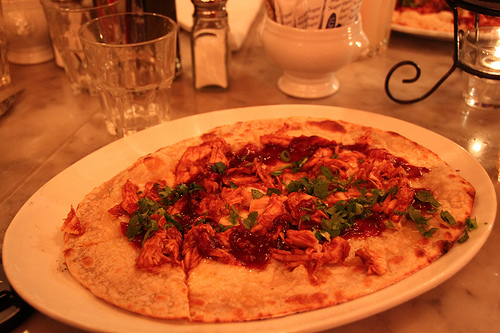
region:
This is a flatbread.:
[45, 75, 477, 328]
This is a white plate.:
[6, 79, 499, 329]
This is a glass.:
[79, 10, 183, 147]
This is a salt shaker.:
[183, 0, 245, 97]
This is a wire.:
[377, 42, 457, 103]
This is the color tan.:
[88, 245, 113, 270]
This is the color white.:
[37, 269, 74, 302]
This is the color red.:
[150, 238, 165, 251]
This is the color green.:
[330, 206, 348, 226]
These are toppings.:
[168, 141, 360, 250]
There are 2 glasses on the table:
[42, 5, 176, 128]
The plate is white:
[67, 126, 465, 292]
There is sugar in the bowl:
[243, 9, 382, 91]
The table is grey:
[367, 62, 489, 184]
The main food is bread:
[128, 138, 431, 299]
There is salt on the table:
[187, 5, 238, 92]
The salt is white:
[187, 10, 254, 110]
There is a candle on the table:
[426, 17, 498, 94]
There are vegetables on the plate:
[135, 162, 475, 239]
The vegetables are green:
[144, 166, 448, 286]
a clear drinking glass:
[78, 8, 177, 128]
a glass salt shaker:
[183, 0, 226, 90]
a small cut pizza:
[61, 130, 460, 327]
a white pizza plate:
[0, 96, 480, 322]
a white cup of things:
[259, 4, 381, 95]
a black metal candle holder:
[378, 0, 499, 107]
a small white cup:
[0, 0, 61, 67]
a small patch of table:
[14, 109, 64, 182]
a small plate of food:
[387, 5, 497, 34]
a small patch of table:
[455, 264, 494, 329]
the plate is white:
[83, 135, 498, 305]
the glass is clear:
[73, 39, 177, 115]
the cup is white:
[268, 37, 355, 84]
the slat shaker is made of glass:
[191, 23, 244, 88]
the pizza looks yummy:
[93, 110, 467, 308]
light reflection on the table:
[461, 115, 498, 150]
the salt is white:
[193, 35, 239, 85]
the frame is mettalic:
[391, 37, 475, 99]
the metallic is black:
[371, 47, 456, 104]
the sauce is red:
[216, 226, 300, 273]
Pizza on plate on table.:
[50, 108, 482, 331]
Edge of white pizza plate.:
[1, 177, 76, 331]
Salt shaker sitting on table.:
[186, 1, 238, 94]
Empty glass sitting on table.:
[69, 8, 184, 132]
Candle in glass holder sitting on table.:
[456, 27, 498, 111]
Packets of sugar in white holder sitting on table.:
[262, 0, 377, 102]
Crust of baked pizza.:
[63, 267, 191, 323]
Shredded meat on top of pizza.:
[130, 223, 347, 272]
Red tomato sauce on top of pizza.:
[227, 228, 276, 275]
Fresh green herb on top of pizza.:
[306, 173, 395, 231]